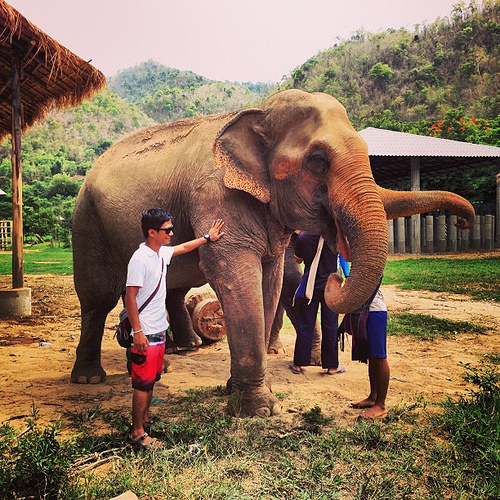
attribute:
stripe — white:
[303, 232, 326, 299]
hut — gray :
[348, 125, 498, 267]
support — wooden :
[423, 214, 435, 251]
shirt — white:
[117, 238, 180, 344]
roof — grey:
[352, 120, 497, 158]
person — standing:
[329, 232, 391, 419]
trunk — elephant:
[322, 171, 392, 315]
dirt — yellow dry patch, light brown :
[1, 274, 498, 499]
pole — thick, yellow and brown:
[8, 49, 30, 294]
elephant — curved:
[61, 68, 406, 440]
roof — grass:
[0, 3, 110, 143]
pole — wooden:
[1, 69, 28, 287]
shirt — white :
[115, 243, 178, 338]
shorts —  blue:
[339, 300, 398, 361]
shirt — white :
[335, 254, 386, 313]